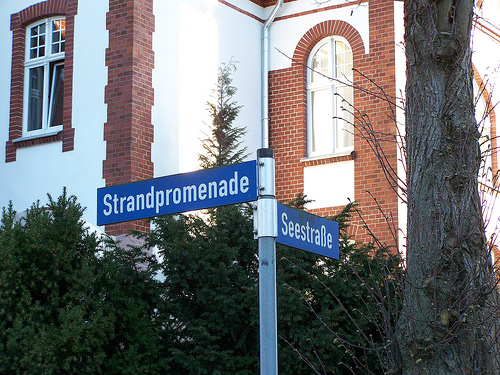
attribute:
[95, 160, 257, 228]
sign — blue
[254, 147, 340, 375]
sign — on a pole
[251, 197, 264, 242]
sign — street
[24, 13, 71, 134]
window — open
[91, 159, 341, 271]
street sign — blue, white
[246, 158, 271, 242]
bolts — metal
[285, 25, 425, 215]
branches — bare, brown, tree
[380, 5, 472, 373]
trunk — tree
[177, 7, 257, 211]
light — white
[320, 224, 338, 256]
letter — white